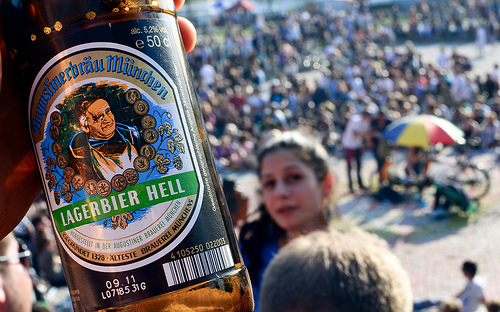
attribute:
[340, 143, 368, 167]
shorts — red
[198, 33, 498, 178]
crowd — people, sitting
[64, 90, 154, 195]
character — cartoon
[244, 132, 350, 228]
woman — smiling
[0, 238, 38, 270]
glasses — silver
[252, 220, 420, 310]
hair — short, dry, gray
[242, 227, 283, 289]
shirt — blue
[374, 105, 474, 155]
umbrella — blue, red, yellow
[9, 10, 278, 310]
bottle — glass, amber, beer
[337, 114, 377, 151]
shirt — white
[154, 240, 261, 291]
barcode — white, black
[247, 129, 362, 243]
girl — pretty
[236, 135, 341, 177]
hair — black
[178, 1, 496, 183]
crowd — people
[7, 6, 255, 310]
bottle — beer, large, brown, empty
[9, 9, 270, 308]
label — black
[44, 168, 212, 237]
stripe — green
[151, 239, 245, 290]
code — black, white, UPC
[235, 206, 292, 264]
hair — long, brown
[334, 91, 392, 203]
person — standing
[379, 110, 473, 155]
umbrella — open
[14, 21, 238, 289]
label — blue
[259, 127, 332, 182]
hair — dark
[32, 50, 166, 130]
writing — blue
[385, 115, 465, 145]
umbrella — multi colored, multicolored, colorful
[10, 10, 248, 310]
beer bottle — brown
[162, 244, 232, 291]
bar code — white